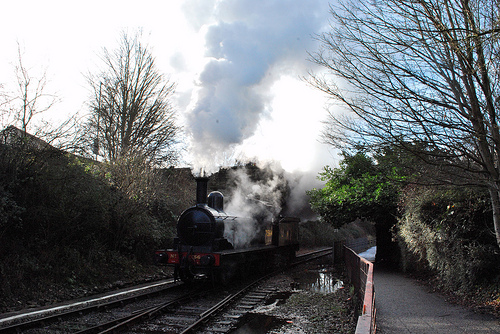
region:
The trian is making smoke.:
[178, 60, 258, 181]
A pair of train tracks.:
[109, 272, 266, 332]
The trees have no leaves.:
[367, 5, 497, 161]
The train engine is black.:
[168, 170, 311, 287]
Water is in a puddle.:
[286, 260, 361, 325]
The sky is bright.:
[27, 11, 89, 78]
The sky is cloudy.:
[39, 8, 225, 61]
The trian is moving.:
[167, 167, 330, 291]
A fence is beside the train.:
[314, 241, 389, 331]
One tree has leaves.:
[315, 140, 431, 230]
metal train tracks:
[105, 300, 240, 330]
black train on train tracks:
[153, 167, 301, 282]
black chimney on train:
[188, 169, 210, 201]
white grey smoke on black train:
[193, 6, 260, 158]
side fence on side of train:
[331, 241, 375, 332]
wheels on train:
[211, 260, 263, 285]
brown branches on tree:
[6, 53, 81, 193]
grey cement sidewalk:
[379, 280, 425, 332]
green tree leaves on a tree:
[308, 152, 430, 267]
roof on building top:
[1, 122, 55, 157]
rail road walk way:
[348, 240, 463, 329]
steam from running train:
[182, 9, 299, 174]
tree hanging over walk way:
[313, 146, 409, 230]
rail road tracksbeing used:
[132, 268, 300, 332]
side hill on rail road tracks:
[3, 149, 170, 256]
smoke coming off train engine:
[217, 179, 310, 265]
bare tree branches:
[317, 11, 499, 231]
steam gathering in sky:
[162, 9, 327, 149]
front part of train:
[166, 205, 228, 274]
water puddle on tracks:
[285, 253, 345, 289]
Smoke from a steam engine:
[185, 88, 237, 171]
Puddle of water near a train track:
[293, 263, 342, 295]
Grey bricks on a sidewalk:
[393, 301, 463, 331]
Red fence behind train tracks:
[333, 240, 378, 290]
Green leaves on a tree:
[307, 157, 394, 221]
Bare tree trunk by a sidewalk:
[482, 90, 499, 247]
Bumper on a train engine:
[153, 247, 219, 269]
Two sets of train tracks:
[13, 281, 266, 327]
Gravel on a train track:
[309, 292, 347, 326]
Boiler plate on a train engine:
[208, 192, 226, 209]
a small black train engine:
[155, 175, 300, 285]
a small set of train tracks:
[15, 245, 336, 330]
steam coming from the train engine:
[185, 0, 340, 175]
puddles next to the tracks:
[231, 256, 341, 328]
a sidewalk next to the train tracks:
[358, 237, 498, 331]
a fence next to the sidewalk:
[333, 232, 382, 332]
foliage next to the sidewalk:
[306, 0, 499, 305]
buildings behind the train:
[1, 124, 265, 214]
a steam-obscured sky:
[0, 0, 498, 175]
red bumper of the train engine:
[153, 250, 218, 265]